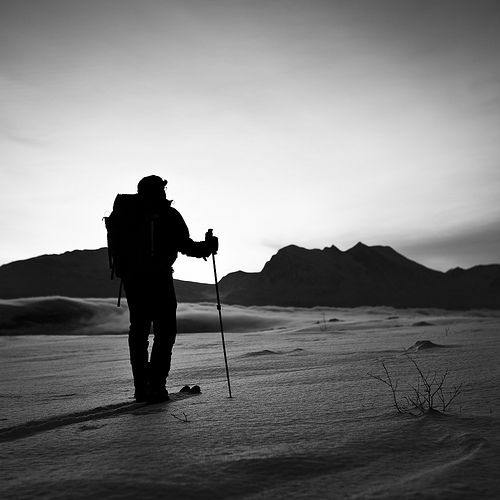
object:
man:
[101, 174, 218, 403]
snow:
[243, 347, 326, 434]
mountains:
[0, 242, 499, 312]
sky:
[60, 43, 295, 157]